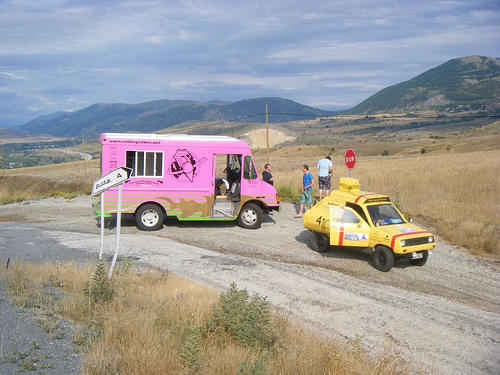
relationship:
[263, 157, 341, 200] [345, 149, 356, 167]
men standing next to stop sign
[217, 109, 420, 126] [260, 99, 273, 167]
power line and pole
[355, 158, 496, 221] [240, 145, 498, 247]
grass in field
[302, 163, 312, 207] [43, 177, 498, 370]
man standing on road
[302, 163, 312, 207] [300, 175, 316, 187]
man wearing blue shirt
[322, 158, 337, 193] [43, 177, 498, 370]
man standing on side road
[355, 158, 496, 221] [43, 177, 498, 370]
grass next to road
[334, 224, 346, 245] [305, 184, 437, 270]
red stripes on yellow car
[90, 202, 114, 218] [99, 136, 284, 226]
green bumper on pink truck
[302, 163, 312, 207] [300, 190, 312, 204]
man in green shorts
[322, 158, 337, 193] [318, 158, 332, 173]
man in light blue shirt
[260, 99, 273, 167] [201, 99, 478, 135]
pole holding wires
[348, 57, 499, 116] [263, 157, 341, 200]
mountain behind people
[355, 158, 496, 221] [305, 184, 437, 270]
long grass next to car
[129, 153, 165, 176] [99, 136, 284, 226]
window on truck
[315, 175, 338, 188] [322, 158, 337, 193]
shorts on man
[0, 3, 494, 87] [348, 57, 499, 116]
sky above mountain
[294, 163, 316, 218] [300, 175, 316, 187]
man in blue shirt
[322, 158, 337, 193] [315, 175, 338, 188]
man in shorts